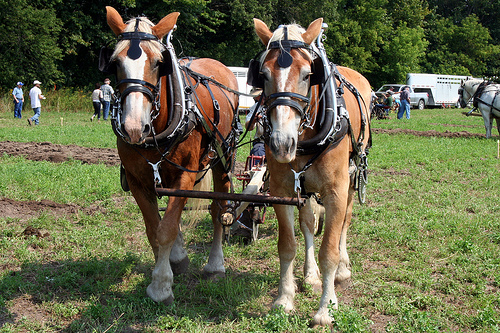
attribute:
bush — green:
[434, 50, 483, 86]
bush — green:
[370, 23, 429, 80]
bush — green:
[220, 0, 255, 70]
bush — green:
[23, 34, 63, 95]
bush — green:
[450, 11, 494, 61]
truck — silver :
[373, 82, 430, 109]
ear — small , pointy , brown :
[153, 8, 180, 42]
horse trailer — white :
[405, 65, 481, 114]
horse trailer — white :
[219, 63, 259, 110]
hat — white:
[33, 77, 40, 84]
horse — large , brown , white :
[248, 17, 371, 331]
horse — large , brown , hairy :
[98, 5, 243, 307]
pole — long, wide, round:
[148, 182, 320, 220]